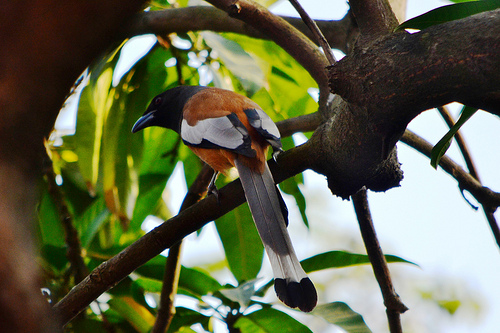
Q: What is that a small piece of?
A: A stem.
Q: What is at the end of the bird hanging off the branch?
A: The tail of the bird.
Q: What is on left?
A: Part of the tree.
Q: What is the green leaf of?
A: The tree.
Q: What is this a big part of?
A: A plant.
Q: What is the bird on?
A: A tree branch.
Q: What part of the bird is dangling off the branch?
A: Its tail.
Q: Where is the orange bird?
A: In a tree.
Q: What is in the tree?
A: An orange bird.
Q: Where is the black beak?
A: On the orange bird.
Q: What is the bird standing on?
A: A branch.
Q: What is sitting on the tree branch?
A: An orange bird.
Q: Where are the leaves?
A: In the background behind the bird.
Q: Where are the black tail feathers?
A: On the tail of the bird.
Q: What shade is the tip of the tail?
A: Black.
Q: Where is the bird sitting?
A: In a tree.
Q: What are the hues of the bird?
A: Black white grey and orange.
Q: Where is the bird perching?
A: On a branch.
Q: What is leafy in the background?
A: Green leaves.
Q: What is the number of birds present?
A: One.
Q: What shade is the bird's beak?
A: Blue.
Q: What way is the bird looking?
A: Left.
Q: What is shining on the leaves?
A: The sun.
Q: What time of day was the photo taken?
A: In the daytime.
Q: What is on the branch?
A: A bird.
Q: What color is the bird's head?
A: Black.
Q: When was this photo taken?
A: Daytime.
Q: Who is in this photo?
A: Nobody.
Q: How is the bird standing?
A: Perched.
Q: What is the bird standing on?
A: A branch.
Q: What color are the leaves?
A: Green.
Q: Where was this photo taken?
A: Under a tree branch.